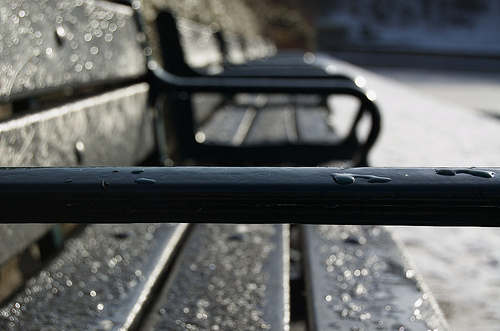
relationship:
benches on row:
[52, 226, 407, 328] [21, 20, 498, 279]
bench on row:
[144, 7, 380, 167] [21, 20, 498, 279]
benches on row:
[0, 0, 449, 330] [21, 20, 498, 279]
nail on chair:
[44, 24, 91, 66] [7, 7, 454, 327]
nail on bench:
[341, 233, 366, 245] [144, 7, 380, 167]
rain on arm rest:
[325, 160, 480, 182] [2, 161, 472, 235]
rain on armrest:
[435, 167, 494, 180] [9, 155, 491, 235]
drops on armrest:
[331, 171, 354, 185] [0, 165, 500, 225]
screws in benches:
[49, 22, 79, 46] [0, 0, 449, 330]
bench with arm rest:
[144, 7, 380, 167] [0, 165, 500, 226]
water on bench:
[66, 11, 109, 76] [144, 7, 380, 167]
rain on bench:
[337, 248, 400, 308] [368, 240, 424, 311]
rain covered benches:
[339, 268, 383, 318] [0, 0, 499, 330]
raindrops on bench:
[208, 270, 256, 325] [157, 12, 392, 172]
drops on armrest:
[331, 169, 404, 196] [7, 162, 498, 221]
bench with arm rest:
[7, 5, 497, 326] [4, 165, 499, 227]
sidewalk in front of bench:
[378, 50, 495, 327] [144, 7, 380, 167]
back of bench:
[1, 0, 165, 261] [144, 7, 380, 167]